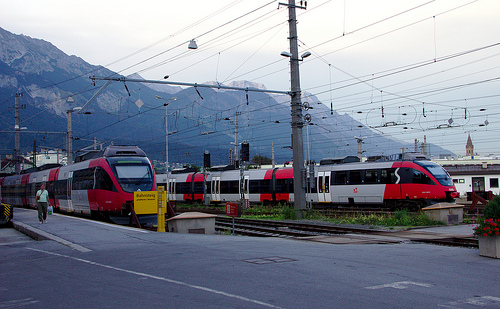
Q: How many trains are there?
A: Two.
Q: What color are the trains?
A: Gray and red.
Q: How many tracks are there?
A: Four.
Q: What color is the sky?
A: Gray.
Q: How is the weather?
A: Cloudy.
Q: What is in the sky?
A: Clouds.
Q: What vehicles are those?
A: Trains.